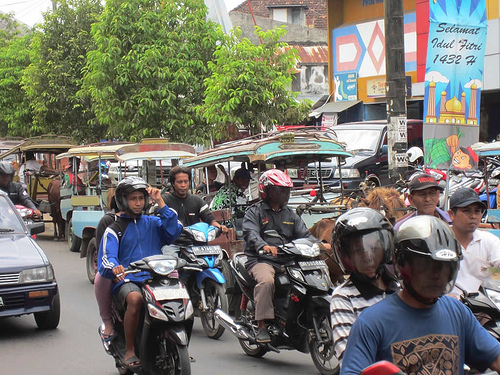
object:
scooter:
[174, 222, 231, 339]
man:
[97, 176, 197, 367]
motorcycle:
[213, 229, 341, 374]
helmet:
[258, 169, 293, 206]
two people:
[94, 176, 195, 367]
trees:
[192, 24, 316, 139]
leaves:
[221, 97, 235, 112]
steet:
[0, 119, 500, 375]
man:
[442, 187, 500, 343]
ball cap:
[450, 187, 488, 208]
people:
[0, 105, 500, 375]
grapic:
[258, 169, 294, 200]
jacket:
[97, 204, 184, 294]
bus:
[160, 123, 355, 240]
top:
[182, 123, 356, 165]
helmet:
[390, 214, 462, 305]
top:
[329, 207, 500, 375]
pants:
[248, 262, 276, 320]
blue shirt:
[340, 292, 500, 375]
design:
[390, 333, 459, 374]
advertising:
[333, 71, 358, 102]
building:
[325, 0, 499, 143]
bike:
[337, 359, 500, 375]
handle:
[359, 359, 500, 375]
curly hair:
[168, 166, 191, 184]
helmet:
[114, 176, 152, 217]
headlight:
[17, 265, 53, 285]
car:
[0, 189, 60, 329]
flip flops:
[123, 351, 142, 368]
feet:
[124, 350, 139, 366]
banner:
[422, 0, 487, 173]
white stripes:
[102, 227, 120, 270]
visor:
[333, 228, 394, 280]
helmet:
[330, 207, 394, 281]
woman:
[329, 207, 394, 369]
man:
[339, 214, 499, 375]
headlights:
[191, 229, 216, 242]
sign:
[330, 13, 416, 103]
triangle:
[367, 21, 385, 50]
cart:
[0, 135, 81, 241]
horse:
[48, 179, 65, 241]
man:
[40, 160, 57, 177]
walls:
[230, 0, 326, 31]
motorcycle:
[98, 254, 203, 374]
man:
[160, 166, 229, 233]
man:
[241, 168, 331, 342]